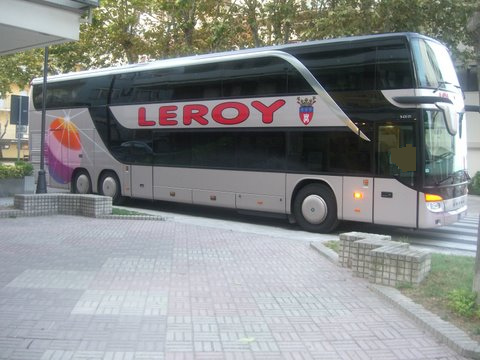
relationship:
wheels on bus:
[67, 166, 121, 207] [25, 27, 471, 228]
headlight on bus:
[421, 182, 455, 226] [25, 27, 471, 228]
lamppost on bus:
[36, 40, 48, 190] [25, 27, 471, 228]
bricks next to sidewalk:
[350, 235, 398, 281] [5, 191, 464, 354]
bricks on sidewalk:
[5, 192, 462, 359] [4, 217, 462, 353]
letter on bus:
[138, 107, 155, 126] [25, 27, 471, 228]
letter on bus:
[180, 97, 212, 127] [25, 27, 471, 228]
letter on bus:
[210, 101, 249, 125] [25, 27, 471, 228]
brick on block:
[411, 276, 418, 282] [336, 230, 429, 287]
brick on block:
[375, 251, 383, 258] [336, 230, 429, 287]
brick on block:
[373, 277, 379, 283] [336, 230, 429, 287]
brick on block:
[350, 271, 355, 276] [336, 230, 429, 287]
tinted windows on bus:
[138, 61, 298, 97] [25, 27, 471, 228]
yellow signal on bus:
[342, 189, 371, 206] [33, 42, 453, 232]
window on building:
[377, 37, 418, 89] [467, 95, 478, 125]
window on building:
[457, 64, 478, 89] [467, 95, 478, 125]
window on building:
[376, 123, 416, 177] [467, 95, 478, 125]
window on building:
[10, 94, 29, 125] [0, 77, 29, 162]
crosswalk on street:
[387, 210, 478, 258] [0, 175, 478, 253]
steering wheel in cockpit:
[432, 153, 453, 162] [386, 114, 465, 176]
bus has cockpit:
[28, 33, 468, 228] [386, 114, 465, 176]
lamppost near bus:
[40, 40, 48, 190] [25, 27, 471, 228]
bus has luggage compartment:
[25, 27, 471, 228] [150, 164, 288, 218]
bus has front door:
[25, 27, 471, 228] [367, 118, 425, 232]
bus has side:
[25, 27, 471, 228] [30, 30, 414, 228]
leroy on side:
[132, 94, 286, 131] [30, 30, 414, 228]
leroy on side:
[136, 98, 284, 128] [30, 30, 414, 228]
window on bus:
[424, 110, 467, 180] [34, 41, 444, 248]